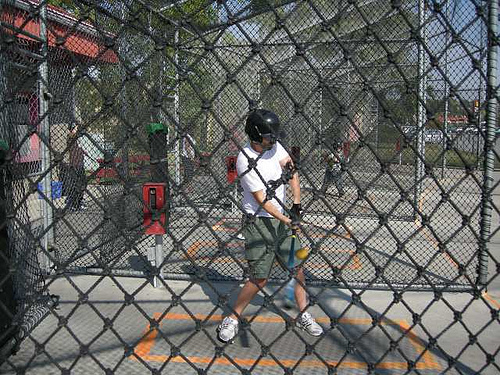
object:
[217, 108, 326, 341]
batter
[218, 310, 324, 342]
shoes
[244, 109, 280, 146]
helmet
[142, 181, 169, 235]
box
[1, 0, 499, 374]
fence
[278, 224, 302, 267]
bat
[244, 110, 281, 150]
head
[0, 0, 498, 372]
cage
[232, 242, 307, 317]
legs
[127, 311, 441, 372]
lines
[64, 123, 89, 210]
person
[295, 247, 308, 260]
baseball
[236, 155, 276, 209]
arms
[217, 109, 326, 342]
boy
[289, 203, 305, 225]
glove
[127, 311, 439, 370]
box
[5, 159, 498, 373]
ground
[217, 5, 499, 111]
sky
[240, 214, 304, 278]
shorts